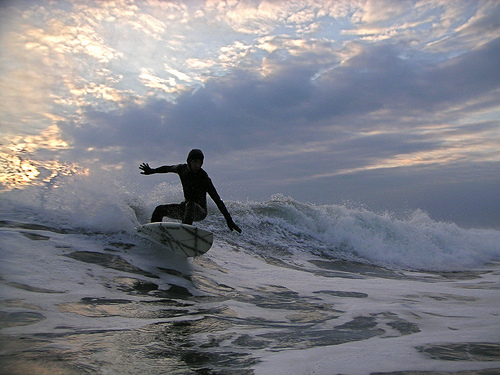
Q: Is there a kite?
A: No, there are no kites.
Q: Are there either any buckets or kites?
A: No, there are no kites or buckets.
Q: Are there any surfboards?
A: Yes, there is a surfboard.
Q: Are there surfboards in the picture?
A: Yes, there is a surfboard.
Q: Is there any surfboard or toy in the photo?
A: Yes, there is a surfboard.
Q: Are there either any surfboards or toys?
A: Yes, there is a surfboard.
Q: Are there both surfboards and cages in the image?
A: No, there is a surfboard but no cages.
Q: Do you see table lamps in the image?
A: No, there are no table lamps.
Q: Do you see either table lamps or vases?
A: No, there are no table lamps or vases.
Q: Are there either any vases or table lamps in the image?
A: No, there are no table lamps or vases.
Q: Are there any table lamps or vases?
A: No, there are no table lamps or vases.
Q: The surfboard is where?
A: The surfboard is on the water.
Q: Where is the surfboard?
A: The surfboard is on the water.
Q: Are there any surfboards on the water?
A: Yes, there is a surfboard on the water.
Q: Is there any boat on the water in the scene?
A: No, there is a surfboard on the water.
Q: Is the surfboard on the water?
A: Yes, the surfboard is on the water.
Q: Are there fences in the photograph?
A: No, there are no fences.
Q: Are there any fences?
A: No, there are no fences.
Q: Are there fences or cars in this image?
A: No, there are no fences or cars.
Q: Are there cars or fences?
A: No, there are no fences or cars.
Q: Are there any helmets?
A: No, there are no helmets.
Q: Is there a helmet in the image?
A: No, there are no helmets.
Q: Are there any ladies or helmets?
A: No, there are no helmets or ladies.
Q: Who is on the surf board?
A: The man is on the surf board.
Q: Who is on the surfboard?
A: The man is on the surf board.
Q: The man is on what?
A: The man is on the surfboard.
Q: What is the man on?
A: The man is on the surfboard.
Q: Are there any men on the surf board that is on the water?
A: Yes, there is a man on the surfboard.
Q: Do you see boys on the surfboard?
A: No, there is a man on the surfboard.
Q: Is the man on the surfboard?
A: Yes, the man is on the surfboard.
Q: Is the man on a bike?
A: No, the man is on the surfboard.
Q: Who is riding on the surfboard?
A: The man is riding on the surfboard.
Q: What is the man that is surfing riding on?
A: The man is riding on the surfboard.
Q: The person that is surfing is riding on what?
A: The man is riding on the surfboard.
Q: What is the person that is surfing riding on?
A: The man is riding on the surfboard.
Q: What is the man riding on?
A: The man is riding on the surfboard.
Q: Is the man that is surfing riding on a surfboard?
A: Yes, the man is riding on a surfboard.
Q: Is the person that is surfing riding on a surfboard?
A: Yes, the man is riding on a surfboard.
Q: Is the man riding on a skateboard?
A: No, the man is riding on a surfboard.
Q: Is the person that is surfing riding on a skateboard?
A: No, the man is riding on a surfboard.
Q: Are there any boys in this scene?
A: No, there are no boys.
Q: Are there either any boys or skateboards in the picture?
A: No, there are no boys or skateboards.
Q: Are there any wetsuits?
A: Yes, there is a wetsuit.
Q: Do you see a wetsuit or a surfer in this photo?
A: Yes, there is a wetsuit.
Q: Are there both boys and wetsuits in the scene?
A: No, there is a wetsuit but no boys.